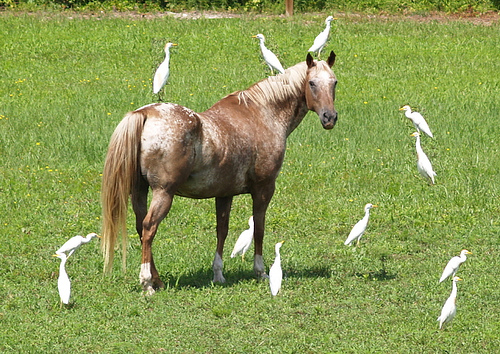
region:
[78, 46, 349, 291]
Horse stand on green grass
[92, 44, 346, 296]
Horse is brown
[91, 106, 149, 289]
Tail of horse is long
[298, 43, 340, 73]
Ears of horse are pointy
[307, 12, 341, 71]
White bird stand on head of horse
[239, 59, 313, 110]
Mane is long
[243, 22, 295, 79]
Bird stand on mane of horse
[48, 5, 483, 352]
Horse surrounded by white birds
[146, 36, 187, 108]
White bird is long and thin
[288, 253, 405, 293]
Shadow cast on grass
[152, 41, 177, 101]
A white bird with an orange beak.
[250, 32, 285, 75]
A white bird with an orange beak.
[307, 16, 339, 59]
A white bird with an orange beak.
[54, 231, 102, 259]
A white bird with an orange beak.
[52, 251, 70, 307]
A white bird with an orange beak.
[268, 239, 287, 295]
A white bird with an orange beak.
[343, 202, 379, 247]
A white bird with an orange beak.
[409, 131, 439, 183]
A white bird with an orange beak.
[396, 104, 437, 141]
A white bird with an orange beak.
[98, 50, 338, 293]
A horse.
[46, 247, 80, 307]
a white pretty bird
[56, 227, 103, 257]
a white pretty bird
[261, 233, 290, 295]
a white pretty bird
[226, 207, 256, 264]
a white pretty bird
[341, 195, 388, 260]
a white pretty bird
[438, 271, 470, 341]
a white pretty bird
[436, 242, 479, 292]
a white pretty bird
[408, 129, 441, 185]
a white pretty bird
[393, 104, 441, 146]
a white pretty bird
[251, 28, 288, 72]
a white pretty bird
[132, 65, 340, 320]
this is a horse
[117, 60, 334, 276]
only one horse seen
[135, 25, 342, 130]
birds are on horse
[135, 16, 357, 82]
three birds on horse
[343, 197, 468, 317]
the birds are white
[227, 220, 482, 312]
the birds are standing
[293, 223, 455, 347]
the grass is green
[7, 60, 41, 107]
the flowers are yellow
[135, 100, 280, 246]
the horse has white patches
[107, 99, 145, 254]
the horse has blonde hair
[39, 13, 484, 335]
horse in a field with birds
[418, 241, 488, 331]
two white birds on the grass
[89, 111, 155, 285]
tail of a horse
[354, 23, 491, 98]
green grass of a field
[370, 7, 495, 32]
dirt path in the background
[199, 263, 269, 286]
front hooves of a horse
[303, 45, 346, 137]
face of a horse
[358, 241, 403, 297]
shadow of bird on the ground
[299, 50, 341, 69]
ears of a horse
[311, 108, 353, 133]
nose and mouth of a horse